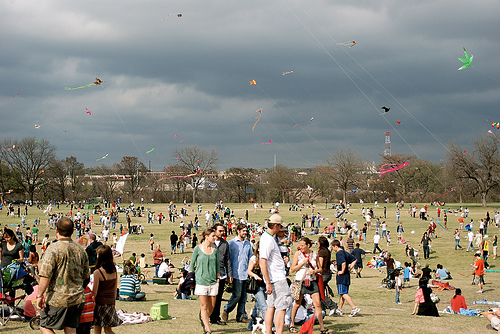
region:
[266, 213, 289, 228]
a tan cap on a man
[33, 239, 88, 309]
a camouflage shirt on a man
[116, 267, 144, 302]
a woman sitting down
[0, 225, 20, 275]
a woman in a black shirt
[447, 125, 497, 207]
a bare leafless tree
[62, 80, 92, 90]
the green tail of a kite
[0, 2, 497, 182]
a dark cloudy sky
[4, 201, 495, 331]
a flat grassy field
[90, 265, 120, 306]
a brown sleeveless shirt on a girl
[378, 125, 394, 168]
a red and white tower in the distance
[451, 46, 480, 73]
a green kite in the sky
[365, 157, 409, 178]
a pink kite in the sky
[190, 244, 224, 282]
a green shirt on a woman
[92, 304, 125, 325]
a plaid skirt on a girl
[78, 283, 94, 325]
an orange and white striped shirt on a boy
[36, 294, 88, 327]
dark gray pants on a man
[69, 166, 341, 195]
buildings in the distance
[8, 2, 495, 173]
a heavy cloudy sky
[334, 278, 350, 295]
blue shorts on a man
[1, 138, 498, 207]
the trees all lined up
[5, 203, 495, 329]
the group of people on the grass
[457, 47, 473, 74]
the green kite in the sky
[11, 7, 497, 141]
the overcast sky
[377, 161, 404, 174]
the hot pink kite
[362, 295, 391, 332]
the short green grass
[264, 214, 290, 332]
the man wearing a white shirt and a hat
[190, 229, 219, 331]
the woman wearing a green long sleeved shirt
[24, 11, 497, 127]
a lot of kites in the sky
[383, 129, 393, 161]
red and white tower in the distance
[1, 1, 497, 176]
Kites flying in the sky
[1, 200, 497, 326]
Crowd at a park for a kite festival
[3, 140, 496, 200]
Trees in the distance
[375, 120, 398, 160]
Radio tower in the distance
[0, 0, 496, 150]
Cloudy sky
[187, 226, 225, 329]
Woman in a green shirt and white shorts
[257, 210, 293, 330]
Man in a white shirt and grey shorts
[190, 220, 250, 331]
People walking across the field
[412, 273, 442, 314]
Woman sitting on the grass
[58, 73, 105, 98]
Colorful kite with green streamer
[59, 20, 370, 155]
a grey cloudy sky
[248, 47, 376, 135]
kites flying in the sky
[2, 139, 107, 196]
trees that are without leaves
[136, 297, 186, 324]
a small green cooler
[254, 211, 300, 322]
a man wearing a baseball cap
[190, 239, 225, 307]
a woman wearing white shorts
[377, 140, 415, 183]
a pink kite in the air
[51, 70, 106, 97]
a kite with a tail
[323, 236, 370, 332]
a kid wearing sneakers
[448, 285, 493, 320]
a woman in an orange shirt